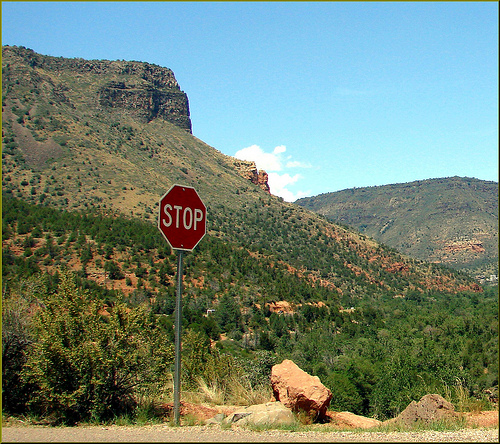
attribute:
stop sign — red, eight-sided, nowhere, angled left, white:
[155, 180, 209, 425]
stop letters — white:
[164, 200, 202, 234]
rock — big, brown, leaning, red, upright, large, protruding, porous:
[265, 356, 333, 422]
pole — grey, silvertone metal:
[173, 245, 184, 427]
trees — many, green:
[1, 123, 499, 415]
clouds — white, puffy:
[231, 135, 319, 207]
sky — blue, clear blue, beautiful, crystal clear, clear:
[5, 5, 493, 196]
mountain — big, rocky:
[0, 37, 291, 399]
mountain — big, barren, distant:
[292, 174, 499, 302]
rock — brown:
[390, 389, 452, 430]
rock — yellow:
[219, 403, 294, 430]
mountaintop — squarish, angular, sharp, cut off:
[9, 28, 202, 129]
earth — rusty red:
[0, 230, 481, 316]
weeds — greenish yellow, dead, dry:
[172, 362, 272, 415]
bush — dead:
[0, 279, 35, 383]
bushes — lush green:
[13, 270, 166, 424]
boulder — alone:
[253, 164, 273, 190]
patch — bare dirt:
[263, 291, 307, 318]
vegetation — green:
[7, 49, 416, 303]